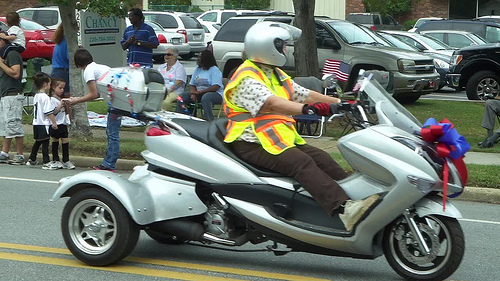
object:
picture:
[0, 0, 499, 281]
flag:
[320, 58, 353, 83]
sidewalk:
[5, 129, 500, 164]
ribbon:
[421, 115, 468, 212]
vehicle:
[46, 71, 464, 279]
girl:
[42, 77, 75, 169]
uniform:
[43, 94, 70, 161]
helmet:
[242, 20, 301, 67]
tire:
[61, 186, 143, 266]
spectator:
[181, 50, 225, 122]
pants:
[222, 138, 350, 215]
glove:
[299, 102, 335, 118]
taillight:
[145, 127, 171, 137]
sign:
[79, 9, 129, 69]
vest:
[221, 58, 308, 154]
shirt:
[79, 60, 112, 91]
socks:
[64, 144, 70, 162]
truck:
[446, 41, 499, 100]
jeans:
[101, 106, 124, 169]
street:
[1, 156, 497, 280]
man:
[117, 8, 159, 68]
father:
[0, 25, 27, 165]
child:
[0, 12, 26, 74]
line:
[2, 238, 353, 280]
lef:
[227, 136, 344, 214]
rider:
[225, 20, 383, 232]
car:
[0, 15, 59, 59]